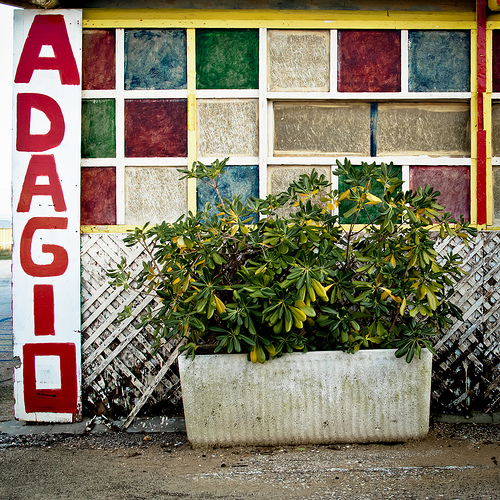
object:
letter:
[12, 13, 82, 87]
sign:
[11, 8, 86, 423]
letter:
[15, 93, 65, 153]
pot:
[176, 346, 434, 449]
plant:
[106, 156, 479, 365]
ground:
[2, 422, 499, 499]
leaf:
[285, 268, 304, 281]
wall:
[80, 0, 499, 232]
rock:
[173, 440, 185, 449]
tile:
[195, 27, 261, 91]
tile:
[195, 97, 259, 159]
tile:
[123, 98, 189, 159]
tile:
[123, 27, 188, 91]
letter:
[19, 217, 68, 279]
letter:
[32, 284, 56, 337]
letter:
[22, 341, 77, 415]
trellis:
[82, 230, 499, 416]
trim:
[81, 9, 478, 234]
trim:
[478, 1, 488, 225]